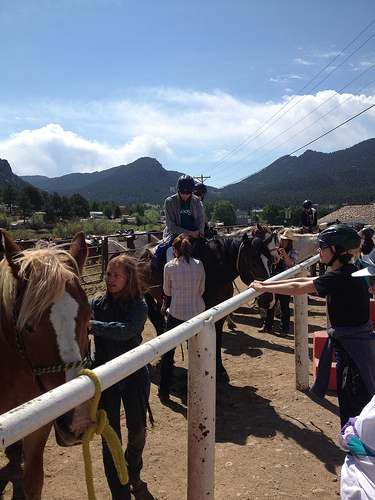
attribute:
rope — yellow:
[76, 367, 129, 499]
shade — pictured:
[238, 406, 283, 466]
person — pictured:
[93, 253, 148, 339]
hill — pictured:
[48, 149, 196, 205]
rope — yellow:
[71, 367, 132, 498]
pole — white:
[3, 249, 321, 498]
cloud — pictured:
[74, 130, 288, 176]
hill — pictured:
[22, 152, 235, 216]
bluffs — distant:
[0, 140, 374, 198]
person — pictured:
[157, 230, 213, 402]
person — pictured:
[252, 223, 372, 419]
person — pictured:
[89, 249, 150, 499]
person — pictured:
[295, 195, 321, 235]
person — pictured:
[254, 225, 304, 339]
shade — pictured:
[248, 418, 274, 436]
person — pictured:
[160, 235, 209, 323]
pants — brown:
[98, 333, 148, 493]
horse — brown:
[0, 256, 125, 467]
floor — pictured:
[208, 412, 300, 487]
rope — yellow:
[41, 370, 146, 485]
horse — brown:
[8, 227, 96, 430]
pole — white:
[3, 254, 320, 444]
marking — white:
[46, 284, 83, 378]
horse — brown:
[2, 226, 103, 495]